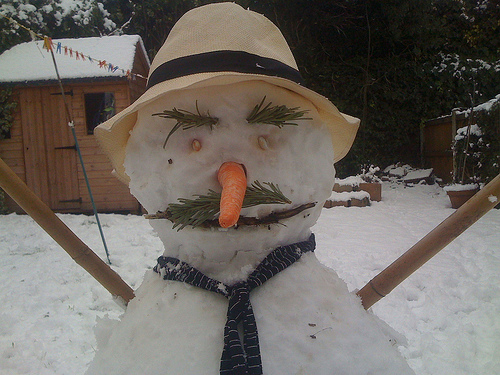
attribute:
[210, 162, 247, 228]
carrot — orange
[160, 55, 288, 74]
band — black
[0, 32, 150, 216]
shed — small, wooden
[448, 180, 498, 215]
pot — snowy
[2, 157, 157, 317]
stick — left side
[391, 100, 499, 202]
fence — wood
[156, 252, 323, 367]
tie — black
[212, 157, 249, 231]
carrot — large, orange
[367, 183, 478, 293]
wooden pole — wooden 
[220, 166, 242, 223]
carrot — orange 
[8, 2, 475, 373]
snowman — dressed up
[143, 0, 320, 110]
hat — soft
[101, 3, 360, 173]
hat — white